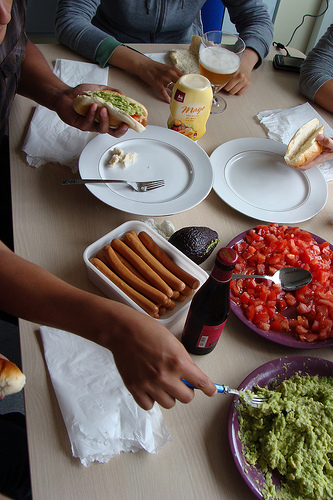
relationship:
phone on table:
[270, 52, 313, 74] [4, 36, 332, 500]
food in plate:
[233, 373, 332, 495] [74, 120, 211, 217]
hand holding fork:
[102, 312, 217, 411] [165, 370, 280, 416]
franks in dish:
[86, 228, 199, 318] [68, 217, 218, 349]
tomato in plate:
[231, 221, 333, 343] [215, 222, 331, 352]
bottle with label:
[180, 240, 242, 357] [194, 317, 228, 355]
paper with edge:
[19, 55, 111, 176] [23, 149, 87, 176]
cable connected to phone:
[272, 1, 332, 52] [270, 52, 313, 74]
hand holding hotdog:
[55, 78, 130, 143] [70, 83, 153, 131]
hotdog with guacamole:
[70, 83, 153, 131] [91, 87, 137, 116]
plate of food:
[225, 349, 332, 500] [233, 373, 332, 495]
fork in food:
[165, 370, 280, 416] [233, 373, 332, 495]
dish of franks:
[68, 217, 218, 349] [86, 228, 199, 318]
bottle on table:
[180, 240, 242, 357] [4, 36, 332, 500]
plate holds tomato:
[215, 222, 331, 352] [231, 221, 333, 343]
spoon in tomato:
[226, 262, 316, 296] [231, 221, 333, 343]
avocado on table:
[169, 221, 227, 266] [4, 36, 332, 500]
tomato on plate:
[231, 221, 333, 343] [215, 222, 331, 352]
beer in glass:
[197, 46, 242, 84] [195, 29, 251, 117]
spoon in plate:
[226, 262, 316, 296] [215, 222, 331, 352]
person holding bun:
[298, 9, 331, 159] [281, 115, 331, 171]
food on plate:
[233, 373, 332, 495] [225, 349, 332, 500]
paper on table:
[19, 55, 111, 176] [4, 36, 332, 500]